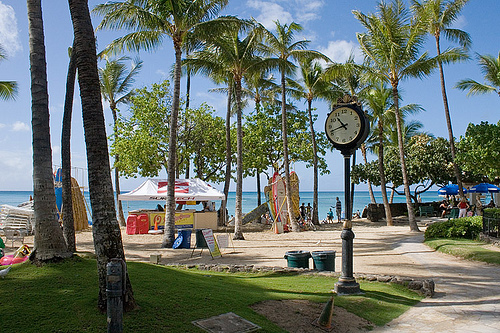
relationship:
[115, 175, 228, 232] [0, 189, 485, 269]
stand on beach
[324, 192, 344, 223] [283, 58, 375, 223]
people between trees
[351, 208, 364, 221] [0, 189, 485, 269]
people by beach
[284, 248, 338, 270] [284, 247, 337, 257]
cans with bags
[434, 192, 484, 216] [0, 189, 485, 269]
people walking to beach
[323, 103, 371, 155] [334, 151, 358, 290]
clock on a pole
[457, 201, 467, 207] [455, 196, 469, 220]
shirt on a lady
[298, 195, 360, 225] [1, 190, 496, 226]
people by water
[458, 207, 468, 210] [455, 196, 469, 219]
hips on a lady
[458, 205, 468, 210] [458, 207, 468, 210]
hands on hips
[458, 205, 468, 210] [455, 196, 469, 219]
hands of lady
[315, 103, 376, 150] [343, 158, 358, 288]
clock on a pole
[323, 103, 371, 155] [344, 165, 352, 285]
clock on a pole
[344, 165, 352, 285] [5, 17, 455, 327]
pole in a park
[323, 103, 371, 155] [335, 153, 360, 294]
clock on a pole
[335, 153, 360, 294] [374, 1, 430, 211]
pole amidst tree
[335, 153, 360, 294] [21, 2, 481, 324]
pole in a park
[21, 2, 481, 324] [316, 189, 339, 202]
park near beach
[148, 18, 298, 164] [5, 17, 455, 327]
trees in a park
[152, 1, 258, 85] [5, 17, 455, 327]
trees in the park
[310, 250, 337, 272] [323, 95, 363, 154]
cans next to clock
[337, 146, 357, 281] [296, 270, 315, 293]
stand on grass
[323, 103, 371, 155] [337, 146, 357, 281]
clock with a stand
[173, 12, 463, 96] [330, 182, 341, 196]
trees near a beach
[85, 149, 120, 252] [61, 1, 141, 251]
trunk of a tree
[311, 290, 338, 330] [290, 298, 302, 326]
cone on dirt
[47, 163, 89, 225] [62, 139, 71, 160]
surfboards leaning against tree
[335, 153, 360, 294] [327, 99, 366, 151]
pole holding up clock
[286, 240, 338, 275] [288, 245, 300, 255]
cans with bags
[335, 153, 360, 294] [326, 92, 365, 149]
pole has clock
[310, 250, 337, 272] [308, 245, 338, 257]
cans has lid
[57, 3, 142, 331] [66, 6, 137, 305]
tree has trunk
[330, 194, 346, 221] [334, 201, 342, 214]
man wearing shirt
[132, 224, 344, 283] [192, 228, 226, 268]
sidewalk has folding sign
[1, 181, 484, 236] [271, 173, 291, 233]
beach has surfboard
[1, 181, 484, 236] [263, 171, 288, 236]
beach has boards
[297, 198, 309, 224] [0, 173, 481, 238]
person standing on beach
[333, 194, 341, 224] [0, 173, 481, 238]
man standing on beach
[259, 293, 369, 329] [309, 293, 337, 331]
dirt has cone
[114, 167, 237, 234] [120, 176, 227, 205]
tent has canopy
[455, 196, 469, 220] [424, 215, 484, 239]
lady wearing bushes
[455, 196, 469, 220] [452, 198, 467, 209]
lady wearing shirt